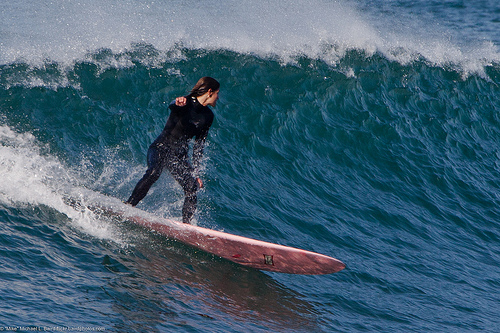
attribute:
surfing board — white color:
[66, 184, 348, 289]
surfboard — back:
[75, 182, 337, 283]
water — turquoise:
[332, 100, 493, 272]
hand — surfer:
[165, 86, 188, 109]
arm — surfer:
[166, 93, 192, 113]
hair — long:
[185, 73, 220, 93]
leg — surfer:
[122, 138, 170, 212]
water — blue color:
[345, 161, 498, 332]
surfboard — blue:
[52, 170, 358, 287]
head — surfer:
[171, 65, 243, 121]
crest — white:
[0, 0, 497, 68]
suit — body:
[136, 95, 206, 204]